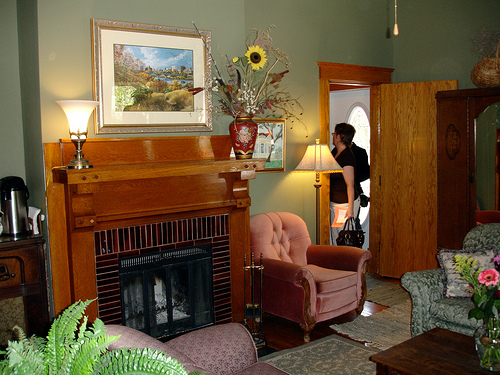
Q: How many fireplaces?
A: One.